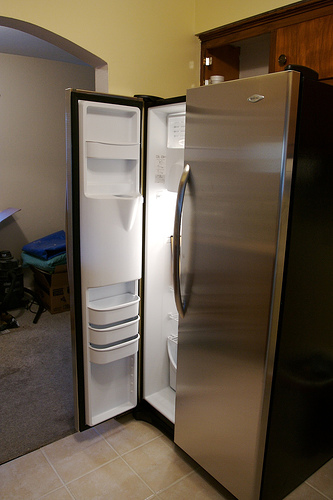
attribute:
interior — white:
[82, 103, 171, 425]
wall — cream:
[3, 0, 292, 96]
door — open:
[64, 88, 144, 431]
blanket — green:
[20, 228, 67, 260]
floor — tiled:
[0, 424, 212, 498]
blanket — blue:
[26, 222, 72, 258]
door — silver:
[56, 83, 265, 447]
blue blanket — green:
[23, 220, 71, 255]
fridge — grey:
[47, 69, 331, 384]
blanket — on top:
[21, 227, 64, 266]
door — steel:
[161, 65, 305, 321]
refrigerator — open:
[38, 53, 331, 458]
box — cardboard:
[12, 254, 72, 309]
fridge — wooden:
[61, 52, 302, 361]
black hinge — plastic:
[286, 62, 316, 78]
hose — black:
[25, 292, 40, 321]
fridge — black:
[170, 69, 331, 498]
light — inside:
[151, 189, 175, 237]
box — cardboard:
[35, 264, 71, 311]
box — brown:
[32, 269, 68, 314]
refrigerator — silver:
[60, 66, 332, 499]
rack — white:
[85, 125, 140, 364]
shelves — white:
[81, 281, 141, 365]